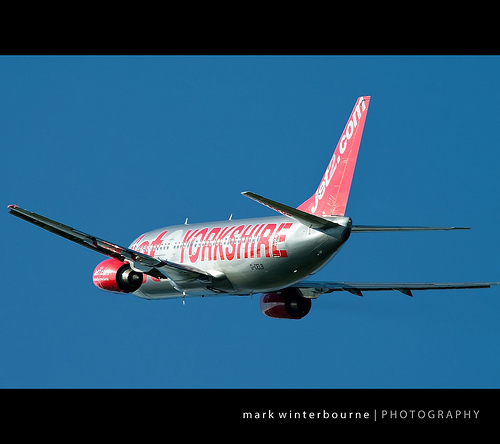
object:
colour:
[331, 157, 335, 178]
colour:
[97, 270, 107, 289]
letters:
[134, 220, 293, 264]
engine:
[89, 255, 146, 295]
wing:
[4, 201, 210, 286]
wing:
[302, 270, 484, 300]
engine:
[255, 287, 324, 325]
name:
[174, 221, 293, 259]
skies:
[1, 54, 500, 388]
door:
[162, 240, 174, 251]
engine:
[91, 255, 314, 322]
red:
[182, 233, 280, 245]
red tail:
[280, 85, 391, 235]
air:
[0, 43, 500, 397]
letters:
[239, 402, 495, 424]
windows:
[125, 240, 275, 252]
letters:
[308, 100, 376, 218]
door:
[269, 232, 279, 258]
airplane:
[6, 80, 497, 322]